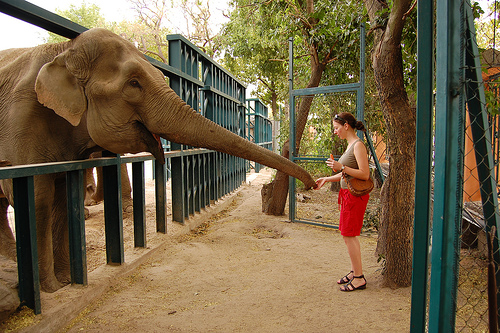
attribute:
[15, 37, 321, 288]
elephant — grey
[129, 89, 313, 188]
trunk — extended, outstretched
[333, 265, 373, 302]
sandals — black, brown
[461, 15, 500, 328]
fence — chain link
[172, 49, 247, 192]
bars — green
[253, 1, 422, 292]
trees — brown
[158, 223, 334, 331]
ground — dirt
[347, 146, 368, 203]
purse — brown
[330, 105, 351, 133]
sunglasses — black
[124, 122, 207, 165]
mouth — open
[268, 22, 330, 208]
tree — leaning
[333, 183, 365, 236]
shorts — red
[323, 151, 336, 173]
carrot — orange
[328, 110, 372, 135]
hair — brown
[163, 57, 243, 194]
fence — green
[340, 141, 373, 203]
tank top — brown